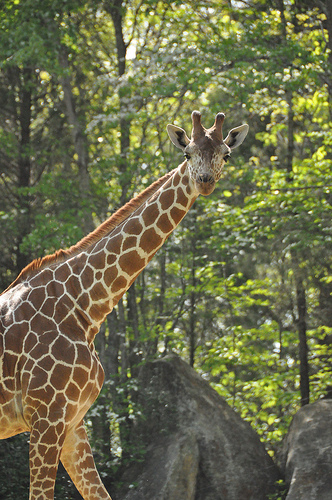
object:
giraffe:
[0, 110, 249, 499]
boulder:
[105, 354, 286, 498]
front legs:
[27, 391, 67, 499]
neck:
[61, 163, 196, 334]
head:
[166, 110, 250, 198]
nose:
[197, 171, 214, 186]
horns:
[191, 110, 207, 139]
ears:
[165, 123, 191, 151]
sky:
[0, 0, 332, 162]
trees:
[243, 0, 323, 409]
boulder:
[276, 396, 332, 498]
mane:
[0, 166, 182, 299]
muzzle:
[193, 163, 219, 197]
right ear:
[165, 123, 189, 154]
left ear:
[223, 120, 252, 152]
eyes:
[182, 151, 193, 163]